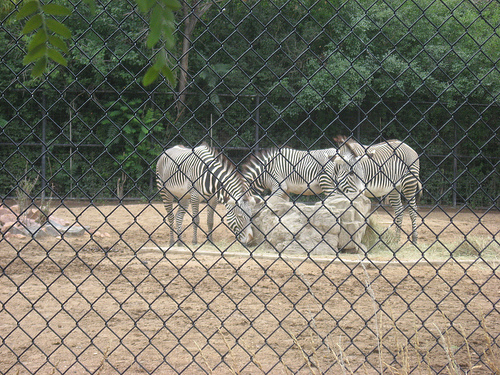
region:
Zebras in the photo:
[143, 113, 426, 253]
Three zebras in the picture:
[127, 107, 420, 254]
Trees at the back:
[242, 32, 429, 141]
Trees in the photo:
[128, 19, 303, 115]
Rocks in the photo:
[268, 199, 332, 249]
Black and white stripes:
[281, 150, 338, 183]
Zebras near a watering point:
[139, 129, 433, 243]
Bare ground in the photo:
[186, 302, 351, 373]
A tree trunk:
[168, 35, 199, 121]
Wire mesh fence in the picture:
[219, 227, 409, 373]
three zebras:
[148, 133, 452, 213]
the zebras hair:
[220, 146, 237, 171]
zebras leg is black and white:
[161, 205, 182, 242]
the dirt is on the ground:
[112, 270, 230, 350]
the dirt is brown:
[43, 263, 163, 339]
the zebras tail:
[412, 177, 427, 193]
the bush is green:
[250, 26, 370, 98]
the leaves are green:
[102, 97, 159, 160]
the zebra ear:
[357, 140, 378, 161]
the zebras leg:
[387, 190, 422, 242]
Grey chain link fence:
[4, 6, 496, 374]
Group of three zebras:
[135, 108, 431, 294]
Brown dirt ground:
[5, 196, 499, 370]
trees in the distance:
[2, 0, 497, 205]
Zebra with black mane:
[325, 123, 363, 176]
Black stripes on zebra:
[156, 135, 267, 265]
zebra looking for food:
[152, 132, 259, 260]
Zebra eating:
[227, 117, 342, 235]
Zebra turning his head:
[326, 125, 428, 277]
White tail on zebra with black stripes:
[407, 159, 429, 206]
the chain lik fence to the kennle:
[1, 3, 150, 365]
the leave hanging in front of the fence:
[0, 8, 185, 88]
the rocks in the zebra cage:
[0, 223, 100, 245]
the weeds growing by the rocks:
[12, 156, 52, 220]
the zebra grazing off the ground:
[157, 141, 257, 254]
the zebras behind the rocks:
[249, 143, 421, 198]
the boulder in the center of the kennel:
[249, 191, 375, 248]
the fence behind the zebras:
[432, 103, 499, 205]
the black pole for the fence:
[35, 84, 51, 197]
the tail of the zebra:
[412, 174, 432, 199]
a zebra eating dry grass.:
[141, 125, 263, 254]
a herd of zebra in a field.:
[144, 96, 444, 271]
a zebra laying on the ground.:
[0, 173, 108, 258]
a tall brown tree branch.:
[166, 11, 195, 125]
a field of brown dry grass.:
[0, 200, 496, 374]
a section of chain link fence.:
[160, 274, 195, 319]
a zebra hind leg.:
[401, 166, 426, 246]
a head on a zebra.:
[221, 185, 263, 247]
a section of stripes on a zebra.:
[280, 159, 308, 179]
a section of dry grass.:
[134, 248, 498, 275]